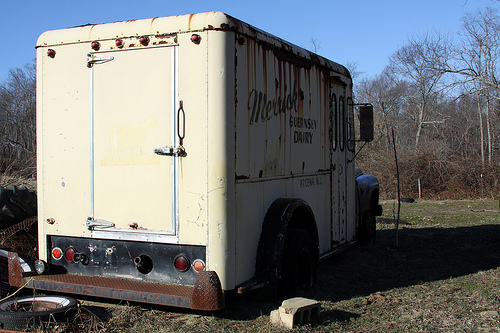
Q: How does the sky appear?
A: Blue and clear.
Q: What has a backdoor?
A: A truck.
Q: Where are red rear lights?
A: On back of truck.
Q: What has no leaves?
A: The trees.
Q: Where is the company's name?
A: On truck.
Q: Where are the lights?
A: Back of truck.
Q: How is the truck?
A: Parked.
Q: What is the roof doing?
A: Rusting.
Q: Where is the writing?
A: Truck side.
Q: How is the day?
A: Sunny.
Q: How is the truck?
A: Rusty.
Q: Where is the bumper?
A: On truck.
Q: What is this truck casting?
A: A shadow.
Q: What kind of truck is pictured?
A: A dairy truck.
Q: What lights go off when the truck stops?
A: The red lights on the bumper.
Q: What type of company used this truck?
A: A dairy.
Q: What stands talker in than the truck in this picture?
A: The trees.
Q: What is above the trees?
A: A clear blue sky.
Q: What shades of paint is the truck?
A: Black and beige.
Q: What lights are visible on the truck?
A: The red lights on the back.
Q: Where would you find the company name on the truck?
A: On the side of the beige truck.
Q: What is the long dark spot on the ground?
A: The trucks shadow.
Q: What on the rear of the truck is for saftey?
A: The bumper.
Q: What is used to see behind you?
A: The sideview mirror.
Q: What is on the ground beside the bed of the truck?
A: A cinderblock.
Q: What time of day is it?
A: Daytime.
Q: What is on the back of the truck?
A: A door.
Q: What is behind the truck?
A: A tire.